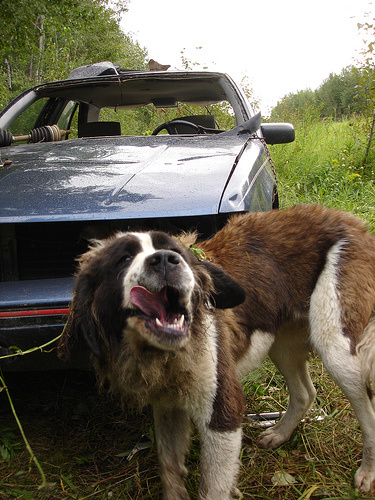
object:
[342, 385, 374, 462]
legs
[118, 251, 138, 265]
eye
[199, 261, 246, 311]
ear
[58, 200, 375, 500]
dog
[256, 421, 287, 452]
paw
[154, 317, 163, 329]
teeth